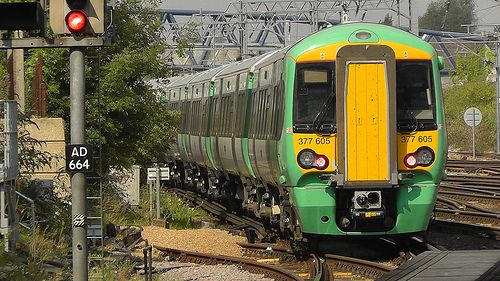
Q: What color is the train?
A: Green.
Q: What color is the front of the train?
A: Yellow.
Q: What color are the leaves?
A: Green.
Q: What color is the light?
A: Red.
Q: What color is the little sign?
A: Black.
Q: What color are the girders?
A: Silver.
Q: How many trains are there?
A: One.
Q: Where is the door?
A: On the engine.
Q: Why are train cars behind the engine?
A: For the passengers.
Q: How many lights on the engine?
A: Four.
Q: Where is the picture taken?
A: Train tracks.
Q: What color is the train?
A: Green and yellow.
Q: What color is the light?
A: Red.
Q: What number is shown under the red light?
A: 664.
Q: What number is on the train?
A: 377605.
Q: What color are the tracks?
A: Brown.